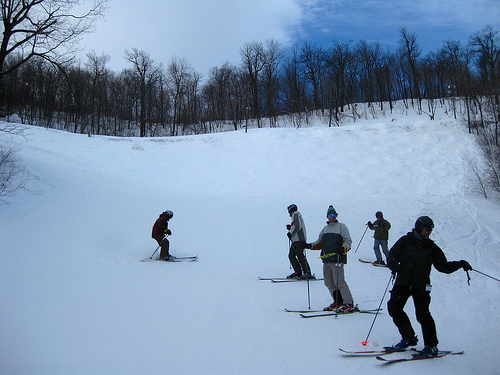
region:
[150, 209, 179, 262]
skier next to skier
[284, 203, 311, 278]
skier next to skier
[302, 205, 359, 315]
skier next to skier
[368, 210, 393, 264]
skier next to skier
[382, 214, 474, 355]
skier next to skier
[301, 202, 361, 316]
skier in front of skier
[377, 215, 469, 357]
skier in front of skier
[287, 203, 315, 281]
skier in front of skier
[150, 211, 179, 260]
skier in front of trees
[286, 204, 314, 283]
skier in front of trees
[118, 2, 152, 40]
white clouds in blue sky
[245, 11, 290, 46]
white clouds in blue sky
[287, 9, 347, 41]
white clouds in blue sky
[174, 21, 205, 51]
white clouds in blue sky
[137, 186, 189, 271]
skier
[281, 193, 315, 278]
skier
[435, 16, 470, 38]
white clouds in blue sky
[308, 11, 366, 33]
white clouds in blue sky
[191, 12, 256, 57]
white clouds in blue sky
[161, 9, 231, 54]
white clouds in blue sky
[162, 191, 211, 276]
person on blue skis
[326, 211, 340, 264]
man wearing gray jacket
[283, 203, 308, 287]
man wearing black pants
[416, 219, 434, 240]
man in black hat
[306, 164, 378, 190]
ripples in white snow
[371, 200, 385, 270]
man in blue pants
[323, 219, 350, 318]
man on skis wearing googles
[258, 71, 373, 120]
grove of sparse trees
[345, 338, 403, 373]
man on red and white skis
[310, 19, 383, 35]
sky is an electric blue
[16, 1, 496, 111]
white cloud in blue sky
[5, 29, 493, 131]
trees with no leaves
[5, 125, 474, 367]
face of snowy slope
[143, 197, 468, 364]
five skiers on snow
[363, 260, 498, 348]
poles in skiers hands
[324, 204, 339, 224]
hat on skiers head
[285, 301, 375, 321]
two skis on snow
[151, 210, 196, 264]
skier bent forward with poles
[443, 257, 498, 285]
pole lifted in the air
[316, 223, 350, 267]
two toned winter jacket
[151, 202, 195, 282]
skier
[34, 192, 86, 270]
white snow on hill side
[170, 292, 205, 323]
white snow on hill side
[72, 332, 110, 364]
white snow on hill side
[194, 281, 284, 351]
white snow on hill side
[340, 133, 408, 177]
white snow on hill side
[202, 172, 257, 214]
white snow on hill side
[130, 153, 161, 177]
white snow on hill side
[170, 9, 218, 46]
white clouds in blue sky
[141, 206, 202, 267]
person skiing toward the right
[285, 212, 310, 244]
white and grey ski jacket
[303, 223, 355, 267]
grey and green ski jacket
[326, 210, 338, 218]
goggles on a person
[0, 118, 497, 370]
slope covered in snow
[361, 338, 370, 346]
orange tip of a ski pole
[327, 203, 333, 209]
ball on top of a ski cap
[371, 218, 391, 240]
green colored ski jacket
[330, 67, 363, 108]
a tree with bare branches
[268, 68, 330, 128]
a tree with bare branches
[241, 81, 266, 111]
a tree with bare branches